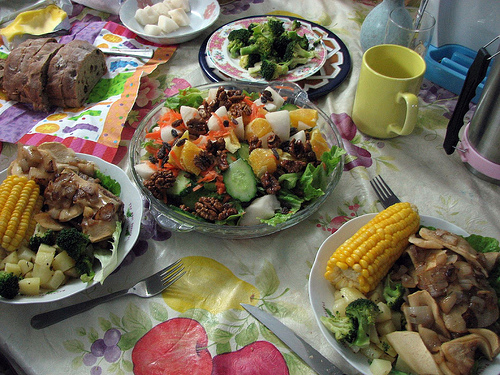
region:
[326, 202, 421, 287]
ear of corn on a plate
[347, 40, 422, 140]
coffee mug on a table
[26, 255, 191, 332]
silver fork on a table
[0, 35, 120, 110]
sliced bread on a napkin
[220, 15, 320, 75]
broccoli sprouts on a plate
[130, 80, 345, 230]
mixed salad on a plate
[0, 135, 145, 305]
plate of food on a table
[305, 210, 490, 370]
plate of food on a table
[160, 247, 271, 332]
picture of a pear on a tablecloth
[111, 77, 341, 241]
a salad in a clear dish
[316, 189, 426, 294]
a ear of corn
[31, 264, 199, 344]
a fork next to a plate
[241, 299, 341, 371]
a knife next to plate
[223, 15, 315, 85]
broccoli on a plate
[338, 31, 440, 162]
a yellow coffee mug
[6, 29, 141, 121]
a sliced loaf of bread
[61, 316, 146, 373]
purple grapes on table cloth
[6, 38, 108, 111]
loaf of bread that's been sliced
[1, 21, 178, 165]
colorful napkin under the loaf of bread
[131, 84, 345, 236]
glass bowl filled with salad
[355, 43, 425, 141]
light green mug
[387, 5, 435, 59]
clear glass behind mug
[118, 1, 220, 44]
white bowl with white food in it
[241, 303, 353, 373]
silver knife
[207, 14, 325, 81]
white and pink plate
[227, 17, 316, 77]
broccoli on the white and pink plate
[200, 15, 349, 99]
dark blue plate under the white and pink plate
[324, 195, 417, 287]
yellow corn on a cobb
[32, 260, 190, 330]
a silver fork on a table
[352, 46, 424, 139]
a yellow cup on atable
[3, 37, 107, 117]
brown bread on a paper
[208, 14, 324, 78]
green broccoli on a plate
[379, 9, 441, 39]
a glass behind the cup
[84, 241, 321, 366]
a fruit covered table cloth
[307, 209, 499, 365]
a plate full of food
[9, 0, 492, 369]
a dinner on a table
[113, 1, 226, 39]
white potatoes in a bowl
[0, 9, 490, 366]
a table full of food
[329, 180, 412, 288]
corn on the plate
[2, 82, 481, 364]
three big plates of food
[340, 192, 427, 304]
the corn is yellow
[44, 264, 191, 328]
a fork on the table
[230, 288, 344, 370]
a knife on the table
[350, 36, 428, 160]
the cup is yellow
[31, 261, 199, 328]
the fork is silver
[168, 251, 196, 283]
the tip of the fork is pointy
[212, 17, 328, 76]
a plate of broccoli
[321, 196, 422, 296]
Ear of yellow corn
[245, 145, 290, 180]
Chunks of oranges in a salad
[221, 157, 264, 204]
Cucumber in a salad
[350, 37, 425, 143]
Yellow coffee mug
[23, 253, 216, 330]
Silver fork on a tablecloth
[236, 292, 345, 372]
Knife on a tablecloth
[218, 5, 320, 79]
Broccoli on a small saucer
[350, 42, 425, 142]
shiny yellow coffee mug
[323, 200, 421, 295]
corn on cob on white plate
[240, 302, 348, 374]
sharp knife resting on tablecloth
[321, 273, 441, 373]
green broccoli and beige potatoes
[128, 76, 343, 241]
salad in a glass bowl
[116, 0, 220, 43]
white food inside of white bowl